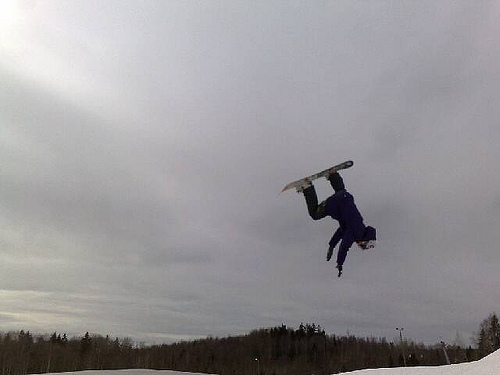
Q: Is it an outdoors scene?
A: Yes, it is outdoors.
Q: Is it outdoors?
A: Yes, it is outdoors.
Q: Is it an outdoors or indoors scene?
A: It is outdoors.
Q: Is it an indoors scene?
A: No, it is outdoors.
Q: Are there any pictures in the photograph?
A: No, there are no pictures.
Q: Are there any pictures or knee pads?
A: No, there are no pictures or knee pads.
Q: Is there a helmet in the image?
A: No, there are no helmets.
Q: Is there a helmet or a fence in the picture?
A: No, there are no helmets or fences.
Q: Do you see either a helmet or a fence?
A: No, there are no helmets or fences.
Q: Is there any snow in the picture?
A: Yes, there is snow.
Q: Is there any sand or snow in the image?
A: Yes, there is snow.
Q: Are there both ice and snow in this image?
A: No, there is snow but no ice.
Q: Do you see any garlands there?
A: No, there are no garlands.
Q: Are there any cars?
A: No, there are no cars.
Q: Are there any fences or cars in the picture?
A: No, there are no cars or fences.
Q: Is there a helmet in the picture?
A: No, there are no helmets.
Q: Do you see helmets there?
A: No, there are no helmets.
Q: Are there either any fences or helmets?
A: No, there are no helmets or fences.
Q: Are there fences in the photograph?
A: No, there are no fences.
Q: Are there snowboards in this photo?
A: Yes, there is a snowboard.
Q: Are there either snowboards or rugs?
A: Yes, there is a snowboard.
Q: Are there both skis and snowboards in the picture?
A: No, there is a snowboard but no skis.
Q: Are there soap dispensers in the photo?
A: No, there are no soap dispensers.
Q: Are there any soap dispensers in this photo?
A: No, there are no soap dispensers.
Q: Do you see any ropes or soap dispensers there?
A: No, there are no soap dispensers or ropes.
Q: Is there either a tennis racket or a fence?
A: No, there are no fences or rackets.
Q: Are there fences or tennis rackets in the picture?
A: No, there are no fences or tennis rackets.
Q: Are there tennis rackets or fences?
A: No, there are no fences or tennis rackets.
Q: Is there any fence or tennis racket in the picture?
A: No, there are no fences or rackets.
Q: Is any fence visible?
A: No, there are no fences.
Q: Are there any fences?
A: No, there are no fences.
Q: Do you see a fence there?
A: No, there are no fences.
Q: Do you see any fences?
A: No, there are no fences.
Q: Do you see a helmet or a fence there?
A: No, there are no fences or helmets.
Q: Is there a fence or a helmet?
A: No, there are no fences or helmets.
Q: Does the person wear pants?
A: Yes, the person wears pants.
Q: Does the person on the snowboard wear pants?
A: Yes, the person wears pants.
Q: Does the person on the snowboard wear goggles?
A: No, the person wears pants.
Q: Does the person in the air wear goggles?
A: No, the person wears pants.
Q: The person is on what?
A: The person is on the snowboard.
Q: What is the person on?
A: The person is on the snowboard.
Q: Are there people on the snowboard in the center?
A: Yes, there is a person on the snowboard.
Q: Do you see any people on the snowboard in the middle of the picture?
A: Yes, there is a person on the snowboard.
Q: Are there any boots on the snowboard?
A: No, there is a person on the snowboard.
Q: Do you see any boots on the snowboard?
A: No, there is a person on the snowboard.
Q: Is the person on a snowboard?
A: Yes, the person is on a snowboard.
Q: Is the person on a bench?
A: No, the person is on a snowboard.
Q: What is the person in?
A: The person is in the air.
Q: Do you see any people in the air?
A: Yes, there is a person in the air.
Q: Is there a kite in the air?
A: No, there is a person in the air.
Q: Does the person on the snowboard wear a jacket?
A: Yes, the person wears a jacket.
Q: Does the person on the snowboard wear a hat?
A: No, the person wears a jacket.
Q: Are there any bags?
A: No, there are no bags.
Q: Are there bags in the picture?
A: No, there are no bags.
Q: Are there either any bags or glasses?
A: No, there are no bags or glasses.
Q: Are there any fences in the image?
A: No, there are no fences.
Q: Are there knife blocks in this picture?
A: No, there are no knife blocks.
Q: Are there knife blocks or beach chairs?
A: No, there are no knife blocks or beach chairs.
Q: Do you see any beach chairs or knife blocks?
A: No, there are no knife blocks or beach chairs.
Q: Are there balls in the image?
A: No, there are no balls.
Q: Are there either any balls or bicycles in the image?
A: No, there are no balls or bicycles.